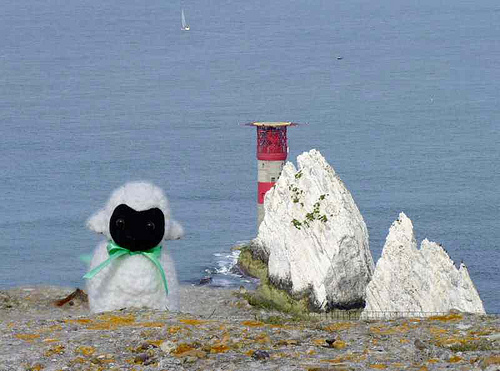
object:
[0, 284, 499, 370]
ground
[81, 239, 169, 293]
ribbon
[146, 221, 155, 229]
eye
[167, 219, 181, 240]
ear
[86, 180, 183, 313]
animal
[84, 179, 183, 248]
haed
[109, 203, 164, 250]
face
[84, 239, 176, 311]
body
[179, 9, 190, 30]
boat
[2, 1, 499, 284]
water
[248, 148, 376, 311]
rock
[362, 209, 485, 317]
rock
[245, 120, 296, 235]
tower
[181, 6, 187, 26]
sail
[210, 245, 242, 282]
waves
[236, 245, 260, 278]
rocks